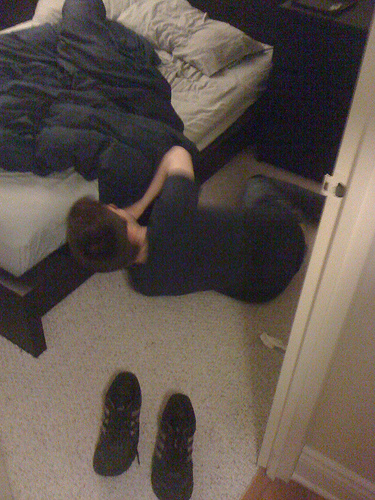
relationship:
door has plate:
[302, 273, 345, 330] [324, 176, 344, 209]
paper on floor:
[255, 330, 290, 354] [99, 288, 348, 464]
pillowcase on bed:
[185, 15, 261, 67] [7, 10, 289, 170]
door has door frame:
[248, 82, 359, 484] [253, 0, 373, 500]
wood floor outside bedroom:
[260, 473, 320, 497] [2, 0, 283, 408]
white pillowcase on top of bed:
[118, 1, 263, 74] [0, 0, 272, 279]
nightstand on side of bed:
[246, 1, 374, 184] [0, 0, 272, 279]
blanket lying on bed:
[0, 1, 201, 226] [0, 0, 272, 279]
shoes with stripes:
[61, 367, 227, 494] [139, 422, 175, 463]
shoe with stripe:
[147, 391, 213, 495] [183, 434, 192, 458]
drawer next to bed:
[263, 67, 348, 141] [16, 9, 274, 175]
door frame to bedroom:
[253, 108, 373, 481] [1, 3, 370, 498]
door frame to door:
[253, 108, 373, 481] [251, 27, 373, 468]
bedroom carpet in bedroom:
[0, 146, 324, 498] [1, 3, 370, 498]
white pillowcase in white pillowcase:
[118, 1, 263, 74] [141, 1, 218, 57]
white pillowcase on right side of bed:
[118, 1, 263, 74] [8, 8, 272, 297]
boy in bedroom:
[67, 146, 313, 332] [1, 3, 370, 498]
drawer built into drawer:
[263, 67, 348, 141] [263, 67, 348, 141]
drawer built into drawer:
[274, 6, 363, 87] [263, 67, 348, 141]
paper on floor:
[255, 330, 290, 354] [79, 291, 288, 382]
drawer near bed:
[263, 67, 348, 141] [0, 4, 252, 151]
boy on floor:
[67, 146, 313, 332] [0, 144, 365, 495]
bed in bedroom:
[0, 0, 272, 279] [8, 66, 372, 456]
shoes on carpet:
[92, 367, 200, 500] [13, 274, 282, 486]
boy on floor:
[67, 146, 313, 332] [2, 283, 305, 498]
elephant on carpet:
[257, 329, 288, 352] [15, 268, 269, 500]